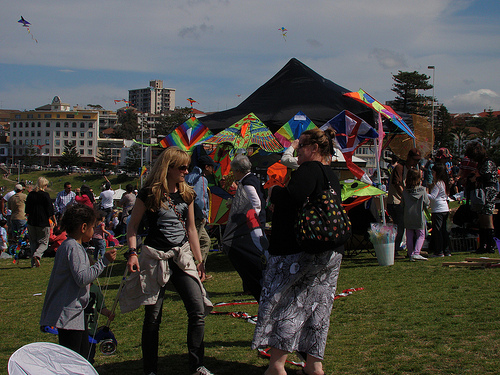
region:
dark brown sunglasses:
[169, 163, 194, 175]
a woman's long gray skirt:
[252, 251, 344, 355]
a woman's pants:
[142, 273, 209, 369]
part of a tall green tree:
[385, 67, 455, 137]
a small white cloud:
[446, 83, 497, 113]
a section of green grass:
[350, 269, 497, 371]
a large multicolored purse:
[297, 177, 356, 254]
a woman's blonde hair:
[30, 175, 52, 193]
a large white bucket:
[372, 240, 395, 264]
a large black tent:
[191, 54, 376, 131]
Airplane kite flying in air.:
[10, 12, 42, 41]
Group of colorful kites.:
[160, 89, 415, 152]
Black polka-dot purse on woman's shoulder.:
[296, 160, 355, 247]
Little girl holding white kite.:
[10, 205, 117, 373]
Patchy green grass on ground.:
[359, 279, 498, 372]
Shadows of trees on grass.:
[43, 170, 133, 187]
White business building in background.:
[11, 104, 100, 166]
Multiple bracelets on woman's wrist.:
[122, 243, 138, 260]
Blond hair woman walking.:
[23, 173, 55, 264]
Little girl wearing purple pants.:
[400, 169, 429, 266]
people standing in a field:
[50, 46, 429, 372]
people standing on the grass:
[28, 57, 360, 373]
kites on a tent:
[104, 8, 499, 229]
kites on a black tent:
[111, 51, 493, 308]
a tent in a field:
[148, 25, 453, 368]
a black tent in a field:
[139, 33, 476, 256]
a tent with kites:
[162, 53, 477, 228]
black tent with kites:
[112, 8, 467, 346]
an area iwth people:
[86, 33, 471, 298]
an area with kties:
[143, 63, 486, 327]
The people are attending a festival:
[1, 20, 491, 360]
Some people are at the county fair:
[10, 37, 478, 372]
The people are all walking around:
[0, 50, 495, 365]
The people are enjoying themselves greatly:
[0, 71, 496, 371]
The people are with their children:
[1, 60, 492, 351]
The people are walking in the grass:
[8, 110, 490, 362]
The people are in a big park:
[1, 95, 487, 360]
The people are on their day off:
[6, 110, 487, 361]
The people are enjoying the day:
[15, 130, 488, 362]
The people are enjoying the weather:
[10, 118, 492, 365]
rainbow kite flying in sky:
[347, 78, 412, 142]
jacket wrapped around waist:
[129, 235, 219, 317]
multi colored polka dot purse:
[292, 176, 354, 247]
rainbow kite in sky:
[157, 115, 213, 153]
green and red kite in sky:
[206, 109, 283, 160]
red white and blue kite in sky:
[319, 108, 376, 148]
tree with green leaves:
[386, 67, 434, 115]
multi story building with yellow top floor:
[7, 113, 93, 154]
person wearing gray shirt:
[42, 237, 109, 336]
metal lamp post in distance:
[424, 61, 438, 182]